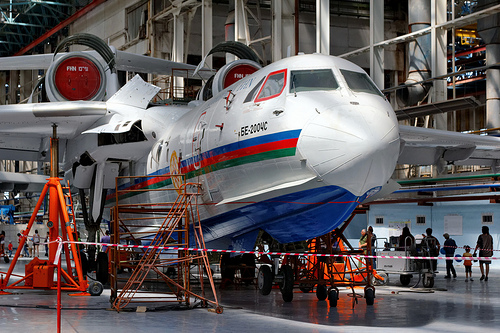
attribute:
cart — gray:
[366, 232, 441, 291]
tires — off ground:
[255, 263, 299, 295]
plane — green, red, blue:
[0, 42, 498, 287]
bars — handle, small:
[223, 90, 233, 108]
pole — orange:
[161, 166, 218, 315]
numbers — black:
[248, 121, 261, 133]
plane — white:
[0, 0, 497, 260]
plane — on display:
[13, 30, 498, 264]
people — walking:
[359, 227, 483, 298]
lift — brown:
[161, 186, 194, 236]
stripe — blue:
[110, 120, 315, 230]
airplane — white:
[17, 30, 498, 277]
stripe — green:
[102, 144, 297, 213]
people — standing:
[256, 181, 488, 281]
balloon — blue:
[448, 249, 460, 261]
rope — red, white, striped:
[48, 233, 497, 274]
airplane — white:
[4, 30, 498, 300]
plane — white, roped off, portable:
[2, 50, 497, 304]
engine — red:
[45, 50, 107, 101]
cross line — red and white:
[61, 240, 499, 259]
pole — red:
[50, 246, 66, 331]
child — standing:
[457, 247, 473, 278]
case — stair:
[115, 189, 226, 319]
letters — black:
[236, 124, 249, 139]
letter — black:
[261, 120, 268, 129]